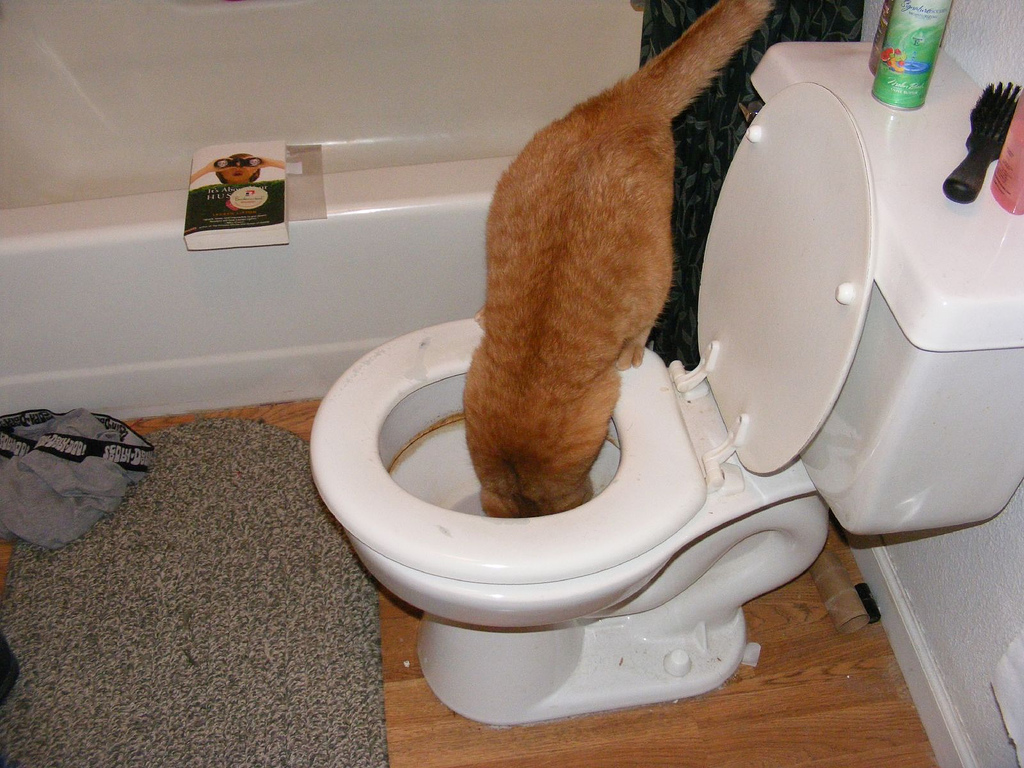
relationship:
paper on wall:
[984, 628, 1016, 761] [863, 495, 1015, 761]